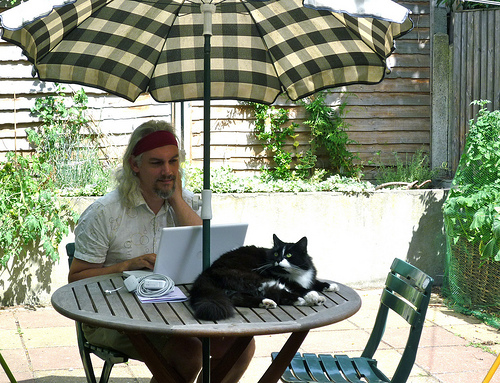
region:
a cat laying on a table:
[187, 230, 338, 318]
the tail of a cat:
[187, 284, 239, 322]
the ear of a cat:
[294, 233, 312, 253]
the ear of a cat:
[270, 229, 282, 249]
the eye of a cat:
[284, 248, 296, 260]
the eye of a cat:
[270, 246, 283, 260]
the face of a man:
[146, 142, 179, 192]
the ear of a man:
[125, 151, 140, 174]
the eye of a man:
[167, 152, 182, 170]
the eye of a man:
[145, 155, 165, 172]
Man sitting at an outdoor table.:
[68, 120, 204, 381]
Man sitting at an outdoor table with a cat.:
[65, 118, 340, 381]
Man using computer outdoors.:
[62, 115, 339, 381]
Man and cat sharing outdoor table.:
[71, 116, 340, 378]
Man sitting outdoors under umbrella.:
[49, 53, 202, 381]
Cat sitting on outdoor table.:
[187, 231, 341, 330]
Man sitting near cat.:
[67, 115, 340, 380]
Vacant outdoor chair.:
[328, 254, 431, 381]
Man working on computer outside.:
[71, 120, 200, 291]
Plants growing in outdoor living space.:
[441, 103, 498, 323]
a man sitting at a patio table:
[71, 120, 253, 382]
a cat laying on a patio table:
[193, 233, 339, 315]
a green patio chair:
[269, 255, 431, 381]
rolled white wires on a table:
[135, 273, 175, 298]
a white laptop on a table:
[121, 221, 248, 280]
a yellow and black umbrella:
[2, 0, 414, 100]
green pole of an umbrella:
[201, 30, 211, 269]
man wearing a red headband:
[126, 126, 178, 157]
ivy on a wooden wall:
[26, 88, 92, 181]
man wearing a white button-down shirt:
[74, 182, 202, 266]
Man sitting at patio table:
[46, 115, 394, 381]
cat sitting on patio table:
[200, 226, 329, 327]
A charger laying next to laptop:
[100, 269, 207, 345]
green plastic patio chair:
[298, 245, 418, 376]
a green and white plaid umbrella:
[6, 2, 432, 123]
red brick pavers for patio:
[343, 303, 483, 381]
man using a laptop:
[74, 112, 256, 274]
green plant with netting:
[445, 100, 498, 323]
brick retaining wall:
[235, 188, 462, 260]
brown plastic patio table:
[56, 270, 363, 380]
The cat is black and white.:
[182, 229, 342, 325]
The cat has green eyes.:
[180, 226, 344, 324]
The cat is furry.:
[185, 226, 342, 328]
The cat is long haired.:
[184, 224, 348, 330]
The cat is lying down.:
[183, 223, 346, 326]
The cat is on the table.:
[47, 223, 373, 381]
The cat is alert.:
[187, 226, 346, 328]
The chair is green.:
[265, 251, 432, 381]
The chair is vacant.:
[265, 245, 432, 380]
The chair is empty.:
[263, 237, 434, 379]